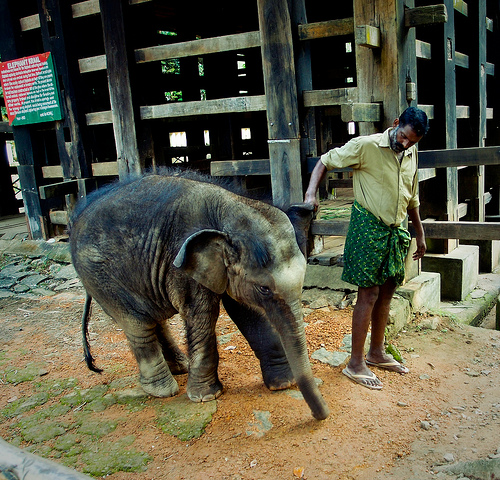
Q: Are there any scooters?
A: No, there are no scooters.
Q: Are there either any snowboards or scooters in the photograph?
A: No, there are no scooters or snowboards.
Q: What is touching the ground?
A: The trunk is touching the ground.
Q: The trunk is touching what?
A: The trunk is touching the ground.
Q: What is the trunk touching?
A: The trunk is touching the ground.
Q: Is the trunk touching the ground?
A: Yes, the trunk is touching the ground.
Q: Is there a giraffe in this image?
A: No, there are no giraffes.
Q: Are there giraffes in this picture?
A: No, there are no giraffes.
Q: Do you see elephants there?
A: Yes, there is an elephant.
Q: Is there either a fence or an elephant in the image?
A: Yes, there is an elephant.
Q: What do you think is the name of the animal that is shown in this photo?
A: The animal is an elephant.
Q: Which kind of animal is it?
A: The animal is an elephant.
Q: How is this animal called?
A: That is an elephant.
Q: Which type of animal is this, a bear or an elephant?
A: That is an elephant.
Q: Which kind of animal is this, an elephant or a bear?
A: That is an elephant.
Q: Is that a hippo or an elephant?
A: That is an elephant.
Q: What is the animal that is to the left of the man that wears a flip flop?
A: The animal is an elephant.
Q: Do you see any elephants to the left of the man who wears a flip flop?
A: Yes, there is an elephant to the left of the man.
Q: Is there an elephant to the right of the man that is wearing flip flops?
A: No, the elephant is to the left of the man.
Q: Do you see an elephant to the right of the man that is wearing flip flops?
A: No, the elephant is to the left of the man.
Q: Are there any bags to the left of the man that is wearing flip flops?
A: No, there is an elephant to the left of the man.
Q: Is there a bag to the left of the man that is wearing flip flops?
A: No, there is an elephant to the left of the man.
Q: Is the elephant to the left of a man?
A: Yes, the elephant is to the left of a man.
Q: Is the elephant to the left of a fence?
A: No, the elephant is to the left of a man.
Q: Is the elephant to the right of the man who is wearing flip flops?
A: No, the elephant is to the left of the man.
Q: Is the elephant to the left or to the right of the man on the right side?
A: The elephant is to the left of the man.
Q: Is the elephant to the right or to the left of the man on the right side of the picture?
A: The elephant is to the left of the man.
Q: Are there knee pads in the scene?
A: No, there are no knee pads.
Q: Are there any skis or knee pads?
A: No, there are no knee pads or skis.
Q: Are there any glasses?
A: No, there are no glasses.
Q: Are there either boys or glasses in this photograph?
A: No, there are no glasses or boys.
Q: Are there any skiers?
A: No, there are no skiers.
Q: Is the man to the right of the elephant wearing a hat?
A: No, the man is wearing a flip flop.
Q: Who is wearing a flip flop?
A: The man is wearing a flip flop.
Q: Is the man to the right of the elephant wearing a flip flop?
A: Yes, the man is wearing a flip flop.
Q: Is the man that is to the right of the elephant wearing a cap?
A: No, the man is wearing a flip flop.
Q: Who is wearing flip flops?
A: The man is wearing flip flops.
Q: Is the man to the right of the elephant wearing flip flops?
A: Yes, the man is wearing flip flops.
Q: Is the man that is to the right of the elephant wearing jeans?
A: No, the man is wearing flip flops.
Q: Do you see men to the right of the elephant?
A: Yes, there is a man to the right of the elephant.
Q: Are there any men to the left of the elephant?
A: No, the man is to the right of the elephant.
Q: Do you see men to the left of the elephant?
A: No, the man is to the right of the elephant.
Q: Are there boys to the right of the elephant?
A: No, there is a man to the right of the elephant.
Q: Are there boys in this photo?
A: No, there are no boys.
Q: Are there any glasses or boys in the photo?
A: No, there are no boys or glasses.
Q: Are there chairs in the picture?
A: No, there are no chairs.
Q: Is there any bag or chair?
A: No, there are no chairs or bags.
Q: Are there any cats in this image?
A: No, there are no cats.